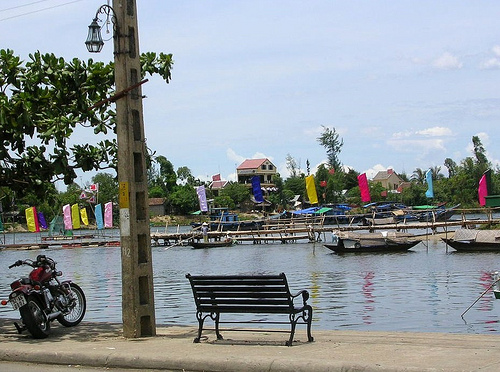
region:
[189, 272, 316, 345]
a bench on a water front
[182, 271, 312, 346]
a black bench on a concrete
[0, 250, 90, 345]
a motorcycle on a water front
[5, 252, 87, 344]
a red motorcycle on concrete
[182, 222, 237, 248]
a boat on the water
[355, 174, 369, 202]
a red flag on a pole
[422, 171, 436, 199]
a blue flag on a pole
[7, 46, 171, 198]
a leafy tree branch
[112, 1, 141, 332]
a concrete gray pole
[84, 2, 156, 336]
a light pole made of concrete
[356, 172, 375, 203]
flag on the pier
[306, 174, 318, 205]
flag on the pier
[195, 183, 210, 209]
flag on the pier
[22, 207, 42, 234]
flag on the pier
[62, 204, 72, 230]
flag on the pier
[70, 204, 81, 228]
flag on the pier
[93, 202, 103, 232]
flag on the pier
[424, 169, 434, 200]
flag on the pier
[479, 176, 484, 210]
flag on the pier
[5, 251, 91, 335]
motorbike parked on the sidewalk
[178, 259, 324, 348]
bench near a lake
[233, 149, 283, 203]
house with a red roof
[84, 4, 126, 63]
black street lamp by the sidewalk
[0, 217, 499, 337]
water in a lake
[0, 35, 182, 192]
tree limb over a bike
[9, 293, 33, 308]
license plate on a bike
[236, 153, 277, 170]
red roof on a building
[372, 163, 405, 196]
house with a grey roof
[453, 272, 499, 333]
stick in the water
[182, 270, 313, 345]
A bench outside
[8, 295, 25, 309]
A license plate on a bike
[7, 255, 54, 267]
Handlebars on a motorcycle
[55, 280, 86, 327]
A front tire on a motorcycle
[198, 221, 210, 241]
Man on the water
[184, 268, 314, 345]
A metal bench outside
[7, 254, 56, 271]
handlebars on a parked bike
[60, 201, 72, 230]
Pink flag on a pole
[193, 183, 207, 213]
Purple flag on a pole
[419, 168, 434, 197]
Light blue flag on a pole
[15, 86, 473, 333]
a docking area for boats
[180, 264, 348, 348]
a bench in the docking area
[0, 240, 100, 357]
a motorcycle parked on the dock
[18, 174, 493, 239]
colorful banners on the docking area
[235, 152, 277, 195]
a structure behind the docking area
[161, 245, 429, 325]
the water is calm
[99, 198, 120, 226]
this banner is pink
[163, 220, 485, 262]
a long pier on the dock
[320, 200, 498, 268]
boats parked next to the dock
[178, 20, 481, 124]
the sky above is cloudy